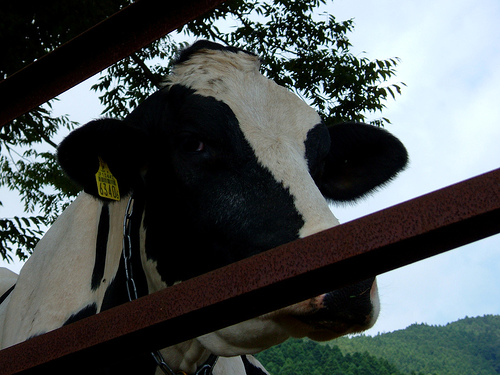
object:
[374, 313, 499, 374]
mountain top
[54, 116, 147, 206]
black ears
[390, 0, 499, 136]
ground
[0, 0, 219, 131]
building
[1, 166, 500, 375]
fence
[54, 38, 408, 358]
head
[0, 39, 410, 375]
cow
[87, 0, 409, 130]
leaves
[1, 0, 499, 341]
sky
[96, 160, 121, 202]
tag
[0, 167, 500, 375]
brown rail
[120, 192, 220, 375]
chain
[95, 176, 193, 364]
neck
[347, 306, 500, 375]
tree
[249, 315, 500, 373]
mountain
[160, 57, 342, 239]
stripe